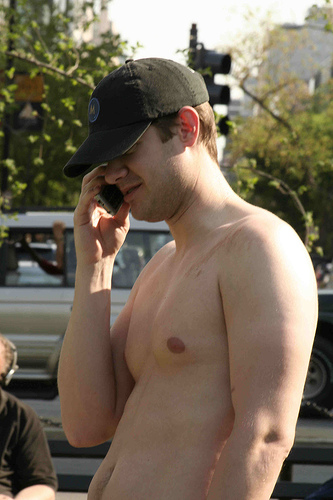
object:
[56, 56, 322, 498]
man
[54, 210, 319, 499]
torso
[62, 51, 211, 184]
cap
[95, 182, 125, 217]
cell phone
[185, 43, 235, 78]
traffic light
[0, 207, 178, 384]
car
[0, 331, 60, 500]
man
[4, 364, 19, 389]
headphones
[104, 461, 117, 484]
belly button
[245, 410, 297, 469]
elbow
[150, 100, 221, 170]
hair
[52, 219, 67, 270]
arm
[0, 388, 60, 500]
shirt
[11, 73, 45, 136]
sign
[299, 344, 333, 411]
tire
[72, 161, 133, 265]
hand